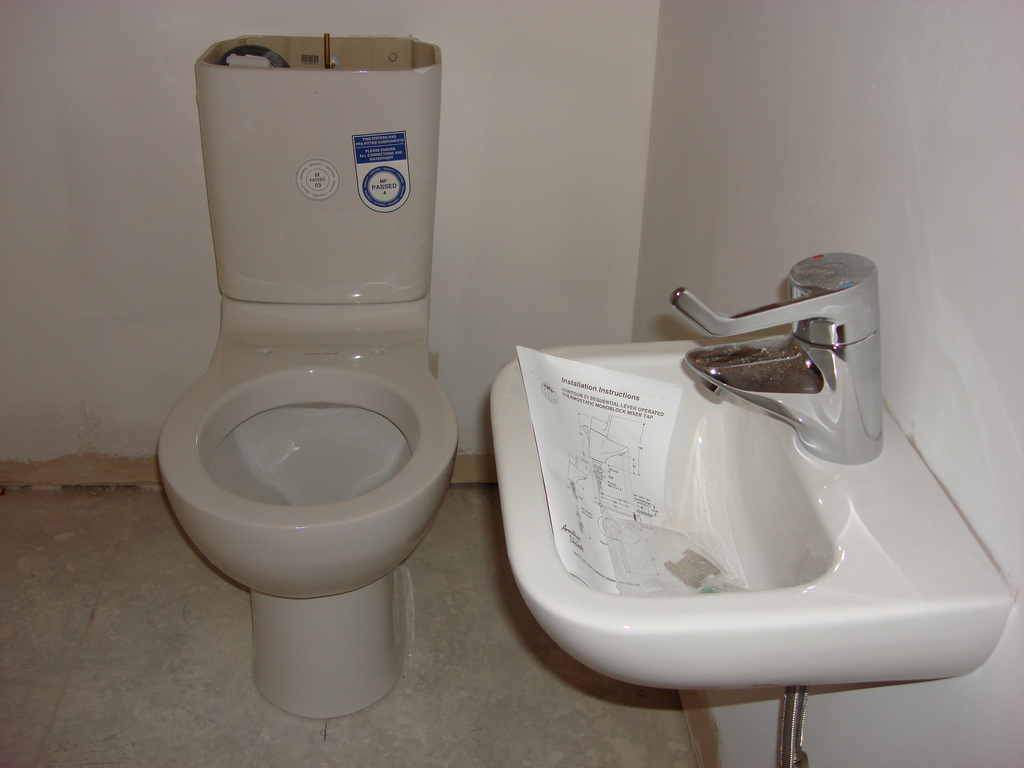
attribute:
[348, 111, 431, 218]
label — blue, white 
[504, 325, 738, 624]
book — instructions, white 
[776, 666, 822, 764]
pipe — silver 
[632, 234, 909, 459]
water faucet — silver , one handled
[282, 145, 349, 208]
sticker — circular , white 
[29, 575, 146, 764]
line — tan 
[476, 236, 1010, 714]
sink — white , small 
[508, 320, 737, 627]
instruction book — white 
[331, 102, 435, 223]
sticker — white , blue 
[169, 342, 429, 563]
bowl — white 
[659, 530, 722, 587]
item — small 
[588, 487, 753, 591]
cover — plastic 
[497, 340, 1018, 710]
sink — white 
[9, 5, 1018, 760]
bathroom — small , white 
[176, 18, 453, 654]
toilet — white 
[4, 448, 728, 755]
floor — dirty , white and gray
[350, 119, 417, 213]
sticker — white and blue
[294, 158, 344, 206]
sticker — round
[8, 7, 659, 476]
wall — unpainted , white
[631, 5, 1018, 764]
wall — white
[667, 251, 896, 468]
faucet — silver